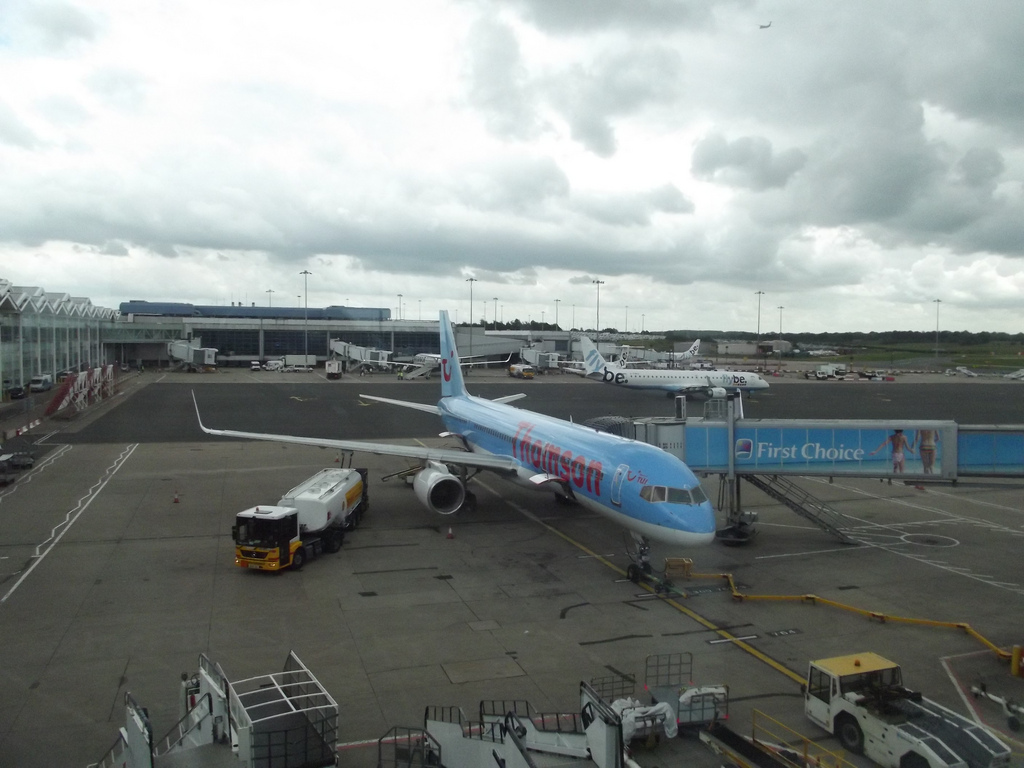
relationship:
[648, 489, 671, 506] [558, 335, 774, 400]
window on a plane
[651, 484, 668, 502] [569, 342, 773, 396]
window on a plane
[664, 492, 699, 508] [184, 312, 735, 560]
window on plane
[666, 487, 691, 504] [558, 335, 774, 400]
window on plane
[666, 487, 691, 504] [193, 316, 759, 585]
window on plane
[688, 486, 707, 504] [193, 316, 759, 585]
window on plane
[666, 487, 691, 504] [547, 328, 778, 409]
window on plane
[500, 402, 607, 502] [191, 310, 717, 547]
lettering on airplane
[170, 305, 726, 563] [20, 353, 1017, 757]
airplane on ground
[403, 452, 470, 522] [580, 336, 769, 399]
engine on airport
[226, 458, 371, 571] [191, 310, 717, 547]
truck near airplane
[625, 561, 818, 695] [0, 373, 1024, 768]
line on ground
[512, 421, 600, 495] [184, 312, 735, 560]
lettering on plane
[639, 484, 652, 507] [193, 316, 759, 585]
window on plane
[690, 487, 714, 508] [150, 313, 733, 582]
window on plane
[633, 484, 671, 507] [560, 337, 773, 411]
window on plane